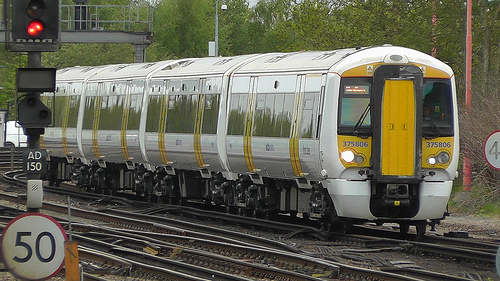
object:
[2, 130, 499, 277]
ground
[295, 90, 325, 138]
windows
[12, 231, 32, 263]
numbers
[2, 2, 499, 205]
background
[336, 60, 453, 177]
front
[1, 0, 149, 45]
building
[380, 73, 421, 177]
rectangle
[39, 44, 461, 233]
train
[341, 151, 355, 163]
lights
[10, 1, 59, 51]
signal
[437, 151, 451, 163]
lights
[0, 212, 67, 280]
sign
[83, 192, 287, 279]
tracks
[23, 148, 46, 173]
sign